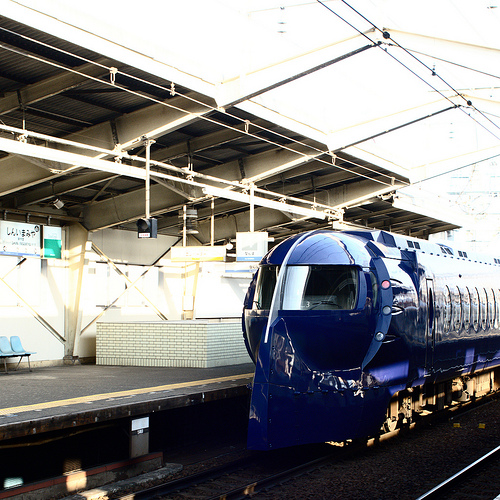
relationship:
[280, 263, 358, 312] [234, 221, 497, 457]
window attached to train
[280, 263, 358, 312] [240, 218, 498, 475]
window attached to train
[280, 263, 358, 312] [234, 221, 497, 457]
window on train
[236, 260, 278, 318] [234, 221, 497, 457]
window on train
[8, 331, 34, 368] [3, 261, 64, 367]
chair by wall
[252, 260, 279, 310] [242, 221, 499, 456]
window on train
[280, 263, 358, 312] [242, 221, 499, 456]
window on train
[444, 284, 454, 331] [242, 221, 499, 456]
window on train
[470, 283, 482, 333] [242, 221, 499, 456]
window on train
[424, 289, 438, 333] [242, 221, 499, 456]
window on train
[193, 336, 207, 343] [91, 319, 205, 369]
brick in wall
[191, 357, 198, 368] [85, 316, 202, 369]
brick in wall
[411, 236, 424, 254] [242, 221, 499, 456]
window on train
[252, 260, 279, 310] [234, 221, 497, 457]
window on train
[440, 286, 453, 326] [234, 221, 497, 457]
window on train